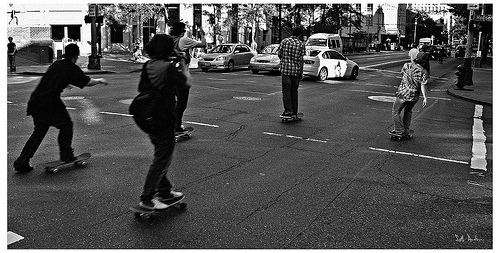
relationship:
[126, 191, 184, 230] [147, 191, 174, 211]
board on foot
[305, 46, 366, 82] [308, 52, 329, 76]
car has shadow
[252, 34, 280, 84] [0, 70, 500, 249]
vehicle in road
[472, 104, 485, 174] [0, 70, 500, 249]
white lines on road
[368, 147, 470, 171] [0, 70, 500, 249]
white lines on road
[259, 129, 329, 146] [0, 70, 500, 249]
white lines on road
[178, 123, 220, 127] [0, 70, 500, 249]
white lines on road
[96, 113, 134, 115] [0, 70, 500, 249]
white lines on road